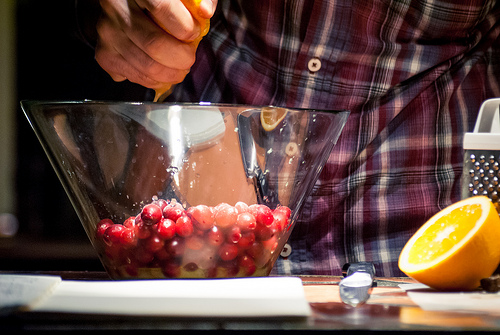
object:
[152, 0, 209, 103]
orange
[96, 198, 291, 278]
grapes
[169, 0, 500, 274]
shirt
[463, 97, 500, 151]
handle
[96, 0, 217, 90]
hand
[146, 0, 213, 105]
fruit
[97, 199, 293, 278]
berries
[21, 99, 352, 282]
glass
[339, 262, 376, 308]
knife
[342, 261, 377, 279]
handle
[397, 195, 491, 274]
skin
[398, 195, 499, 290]
fruit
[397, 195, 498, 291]
half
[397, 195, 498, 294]
orange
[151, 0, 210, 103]
cut half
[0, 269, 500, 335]
cutting board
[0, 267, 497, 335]
counter top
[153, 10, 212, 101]
orange jucie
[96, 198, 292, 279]
bunch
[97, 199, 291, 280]
cherries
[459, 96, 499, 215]
food grater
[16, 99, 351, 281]
bowl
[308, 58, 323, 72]
button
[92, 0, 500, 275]
man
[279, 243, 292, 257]
button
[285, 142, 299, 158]
button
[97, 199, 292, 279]
cranberries